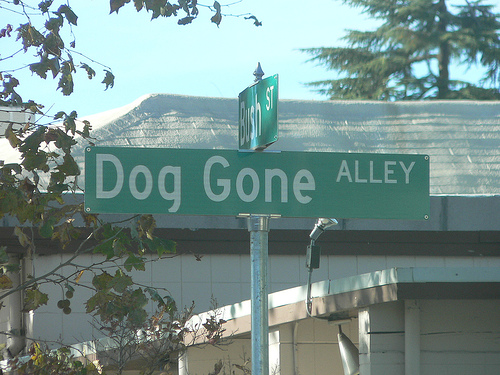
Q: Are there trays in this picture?
A: No, there are no trays.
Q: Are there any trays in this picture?
A: No, there are no trays.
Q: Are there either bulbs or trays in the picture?
A: No, there are no trays or bulbs.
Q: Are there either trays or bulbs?
A: No, there are no trays or bulbs.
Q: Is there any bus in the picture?
A: No, there are no buses.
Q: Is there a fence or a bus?
A: No, there are no buses or fences.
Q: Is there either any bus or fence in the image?
A: No, there are no buses or fences.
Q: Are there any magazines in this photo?
A: No, there are no magazines.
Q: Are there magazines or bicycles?
A: No, there are no magazines or bicycles.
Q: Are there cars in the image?
A: No, there are no cars.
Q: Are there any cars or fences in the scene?
A: No, there are no cars or fences.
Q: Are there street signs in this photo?
A: Yes, there is a street sign.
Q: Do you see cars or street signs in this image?
A: Yes, there is a street sign.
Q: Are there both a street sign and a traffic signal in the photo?
A: No, there is a street sign but no traffic lights.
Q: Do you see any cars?
A: No, there are no cars.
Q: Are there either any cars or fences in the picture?
A: No, there are no cars or fences.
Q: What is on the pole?
A: The street sign is on the pole.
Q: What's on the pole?
A: The street sign is on the pole.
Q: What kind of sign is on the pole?
A: The sign is a street sign.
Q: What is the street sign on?
A: The street sign is on the pole.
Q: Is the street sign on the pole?
A: Yes, the street sign is on the pole.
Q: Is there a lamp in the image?
A: Yes, there is a lamp.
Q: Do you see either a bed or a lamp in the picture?
A: Yes, there is a lamp.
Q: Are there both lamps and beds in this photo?
A: No, there is a lamp but no beds.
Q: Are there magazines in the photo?
A: No, there are no magazines.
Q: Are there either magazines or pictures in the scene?
A: No, there are no magazines or pictures.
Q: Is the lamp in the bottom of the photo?
A: Yes, the lamp is in the bottom of the image.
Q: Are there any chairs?
A: No, there are no chairs.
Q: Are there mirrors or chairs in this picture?
A: No, there are no chairs or mirrors.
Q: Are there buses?
A: No, there are no buses.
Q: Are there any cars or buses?
A: No, there are no buses or cars.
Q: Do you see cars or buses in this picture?
A: No, there are no buses or cars.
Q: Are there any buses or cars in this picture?
A: No, there are no buses or cars.